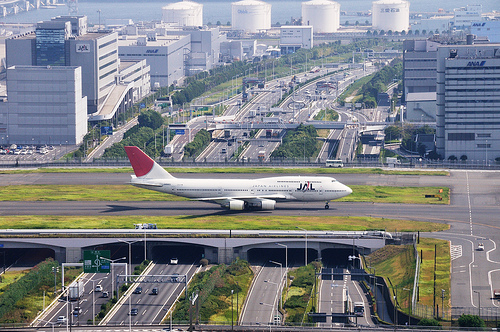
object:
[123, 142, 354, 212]
plane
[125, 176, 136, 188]
wing tip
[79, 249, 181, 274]
traffic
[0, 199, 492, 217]
runway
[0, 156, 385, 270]
bridge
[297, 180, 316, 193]
logo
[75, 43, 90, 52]
logo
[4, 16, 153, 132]
building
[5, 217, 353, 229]
grass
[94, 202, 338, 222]
shadow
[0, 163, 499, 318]
ground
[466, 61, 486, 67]
logo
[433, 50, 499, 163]
building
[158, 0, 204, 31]
structures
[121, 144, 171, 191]
tail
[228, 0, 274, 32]
tanks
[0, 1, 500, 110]
background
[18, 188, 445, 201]
grass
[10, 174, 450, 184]
runway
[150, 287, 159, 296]
cars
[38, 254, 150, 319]
highway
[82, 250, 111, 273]
sign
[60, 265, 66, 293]
pole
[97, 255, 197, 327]
highway